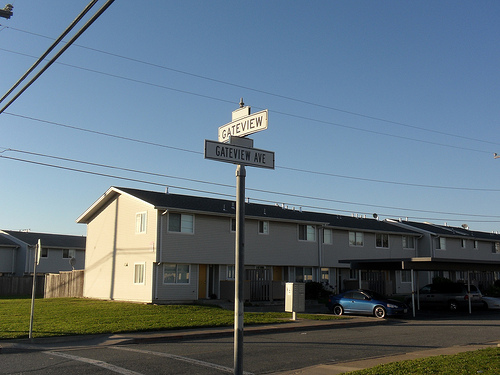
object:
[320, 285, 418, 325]
car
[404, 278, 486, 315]
van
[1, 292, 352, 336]
grass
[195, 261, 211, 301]
door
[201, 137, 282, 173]
sign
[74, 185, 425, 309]
house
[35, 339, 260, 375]
stripes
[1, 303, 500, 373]
road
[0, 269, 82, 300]
fence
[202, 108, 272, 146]
signs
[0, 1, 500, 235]
sky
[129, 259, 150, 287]
window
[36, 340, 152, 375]
lines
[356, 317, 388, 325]
curb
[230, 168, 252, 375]
pole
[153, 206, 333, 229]
gutter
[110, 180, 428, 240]
roof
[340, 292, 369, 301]
window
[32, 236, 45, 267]
sign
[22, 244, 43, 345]
pole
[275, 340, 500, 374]
sidewalk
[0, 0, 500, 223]
wires